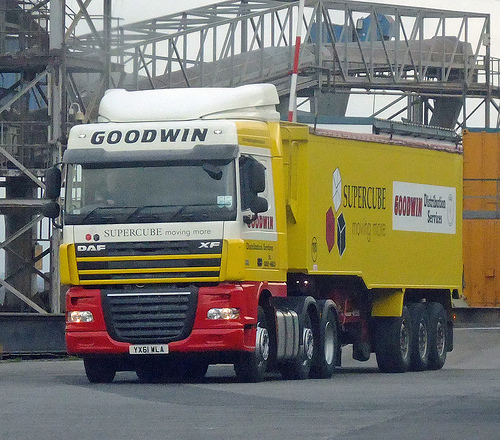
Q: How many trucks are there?
A: One.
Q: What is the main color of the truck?
A: Yellow.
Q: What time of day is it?
A: Morning.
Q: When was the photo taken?
A: Daytime.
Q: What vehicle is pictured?
A: A truck.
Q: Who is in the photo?
A: Nobody.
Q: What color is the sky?
A: Grey.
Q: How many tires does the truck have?
A: Twelve.